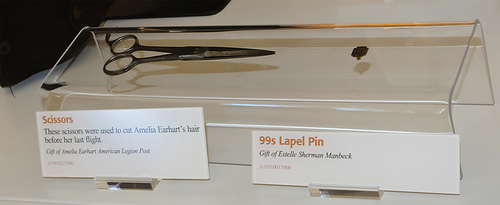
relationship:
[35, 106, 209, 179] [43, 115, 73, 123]
card has text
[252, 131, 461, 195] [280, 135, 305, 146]
card has text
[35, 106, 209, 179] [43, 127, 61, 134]
card has text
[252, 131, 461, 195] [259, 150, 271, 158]
card has text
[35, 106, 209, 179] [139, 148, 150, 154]
card has text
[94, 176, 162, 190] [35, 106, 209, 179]
card holder holds card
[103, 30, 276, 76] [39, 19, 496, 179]
scissors are on display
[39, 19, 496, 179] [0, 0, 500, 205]
display on table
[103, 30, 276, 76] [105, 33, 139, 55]
scissors has handle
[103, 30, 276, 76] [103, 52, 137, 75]
scissors has handle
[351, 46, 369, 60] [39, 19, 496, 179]
lapel pin on display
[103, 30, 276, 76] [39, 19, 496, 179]
scissors are on top of display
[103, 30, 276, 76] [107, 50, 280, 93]
scissors has reflection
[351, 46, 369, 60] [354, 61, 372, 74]
lapel pin has reflection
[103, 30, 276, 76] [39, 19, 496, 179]
scissors are laying on display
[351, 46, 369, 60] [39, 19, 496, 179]
lapel pin laying on display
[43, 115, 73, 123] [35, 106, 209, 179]
text on card